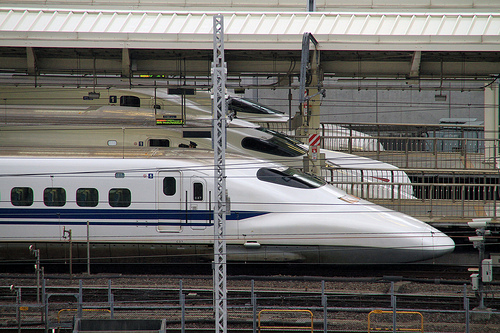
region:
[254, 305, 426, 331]
Two yellow metal railings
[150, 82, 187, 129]
Hanging neon sign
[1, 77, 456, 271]
Three white subway trains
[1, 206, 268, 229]
Blue stripe on the side of a train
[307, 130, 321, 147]
White and red striped square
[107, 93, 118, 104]
Arrow pointing up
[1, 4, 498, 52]
White metal awning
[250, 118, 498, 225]
Gray metal gates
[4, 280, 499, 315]
Black train tracks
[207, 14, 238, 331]
Tall gray metal pole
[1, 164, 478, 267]
white train on track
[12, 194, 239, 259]
blue stripe on train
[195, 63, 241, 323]
grey pole in front of train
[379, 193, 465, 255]
white tip of train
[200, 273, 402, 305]
brown gravel on tracks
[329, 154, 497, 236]
grey rail behind train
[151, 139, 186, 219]
white and blue doors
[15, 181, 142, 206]
small square windows on train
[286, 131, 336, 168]
red and white caution sign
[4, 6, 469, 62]
white roof of building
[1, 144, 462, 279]
a bullet train passing by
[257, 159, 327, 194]
windshield of a train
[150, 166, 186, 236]
door of a speeding train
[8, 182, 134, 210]
window of a bullet train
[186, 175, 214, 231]
door to a bullet train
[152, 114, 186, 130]
an electronic display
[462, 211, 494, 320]
bunch of sensors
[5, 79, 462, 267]
bunch of bullet trains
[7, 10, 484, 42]
roof of a train station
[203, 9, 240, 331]
a steel pillar poll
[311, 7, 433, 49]
white tiles on roof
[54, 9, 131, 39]
rows of lines on roof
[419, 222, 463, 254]
bullet front of train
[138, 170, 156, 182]
tiny blue sign on train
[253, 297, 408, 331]
orange barriers at side of track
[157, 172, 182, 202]
window in door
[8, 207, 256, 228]
dark blue line at side of train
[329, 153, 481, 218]
long silver barriers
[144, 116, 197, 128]
neon green and red words on billboard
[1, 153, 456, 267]
A white train with a blue stripe.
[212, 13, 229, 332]
A tall metal grey pole.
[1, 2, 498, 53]
A white roof on a building.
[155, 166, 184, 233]
A larger white door on a white train.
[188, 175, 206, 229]
A smaller white door on a train.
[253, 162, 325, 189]
A front black window of a white and blue train.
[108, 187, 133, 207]
The first black window by a door.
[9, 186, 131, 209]
Four black windows on a white and blue train.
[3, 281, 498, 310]
Brown train tracks that are empty.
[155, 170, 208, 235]
Two doors not of the same size on the white and blue train.